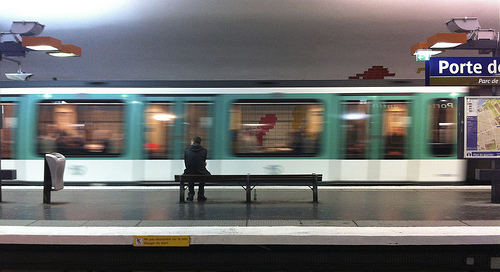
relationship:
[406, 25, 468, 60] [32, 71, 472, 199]
light above train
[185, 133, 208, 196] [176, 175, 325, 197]
man sitting on bench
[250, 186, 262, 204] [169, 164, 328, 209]
bottle near bench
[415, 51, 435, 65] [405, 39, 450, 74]
sign with arrow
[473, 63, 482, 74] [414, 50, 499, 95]
e on sign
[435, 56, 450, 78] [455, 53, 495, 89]
letter p on sign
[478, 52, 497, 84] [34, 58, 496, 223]
letter o on train